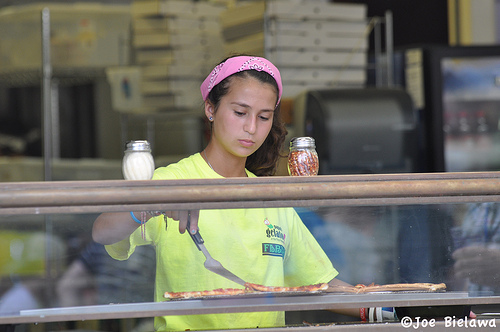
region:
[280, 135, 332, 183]
red pepper shaker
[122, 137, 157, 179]
shaker filled with Parmesan cheese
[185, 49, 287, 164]
girl wearing pink head band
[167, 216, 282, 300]
metal spatula scooping pizza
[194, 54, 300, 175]
girl with hair tied back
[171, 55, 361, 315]
girl scooping a slice of pizza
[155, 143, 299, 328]
yellow tshirt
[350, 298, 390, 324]
two white wristbands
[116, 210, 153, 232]
one blue wristband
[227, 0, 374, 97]
stack of white pizza boxes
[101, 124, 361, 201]
Cheese and pepper shakers.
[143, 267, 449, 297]
A pizza.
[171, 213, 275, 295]
A metal spatula.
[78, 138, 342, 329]
Her shirt is yellow.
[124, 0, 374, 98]
A stack of boxes in the background.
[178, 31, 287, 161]
She is wearing a pink hair band.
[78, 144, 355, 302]
She is getting a slice of pizza.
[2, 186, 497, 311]
A glass guard is in front.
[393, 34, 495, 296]
A soda machine is in the background.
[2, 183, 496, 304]
Other people can be seen in the glass.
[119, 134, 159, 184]
glass shaker of parmesan cheese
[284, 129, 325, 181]
glass shaker of red pepper flakes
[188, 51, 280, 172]
girl with a pink kerchief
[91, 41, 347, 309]
girl scooping up a piece of pizza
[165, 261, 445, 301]
pizza in a warming tray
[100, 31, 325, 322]
girl in a yellow shirt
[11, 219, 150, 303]
people in a pizza restaurant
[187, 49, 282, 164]
brunette with blue earrings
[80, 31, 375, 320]
girls working in a pizza restaurant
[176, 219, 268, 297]
triangular pizza spatula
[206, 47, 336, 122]
Pink bandana on girl's head.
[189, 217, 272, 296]
Girl wearing yellow shirt.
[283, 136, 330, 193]
Red pepper flakes on counter.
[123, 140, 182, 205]
White cheese in container.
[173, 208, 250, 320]
Girl holding spatula.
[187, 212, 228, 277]
Spatula has black handle.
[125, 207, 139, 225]
Girl is wearing blue bracelet.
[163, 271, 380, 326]
Pizza on tray.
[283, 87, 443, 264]
Paper towel holder behind girl.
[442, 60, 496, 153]
Beverage cooler to the right of girl.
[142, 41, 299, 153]
pink headband around girl's head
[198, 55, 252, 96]
pink headband around girl's head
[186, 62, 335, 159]
pink headband around girl's head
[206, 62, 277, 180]
pink headband around girl's head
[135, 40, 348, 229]
pink headband around girl's head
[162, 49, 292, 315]
pink headband around girl's head